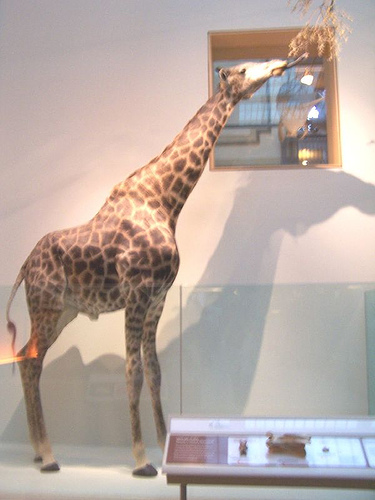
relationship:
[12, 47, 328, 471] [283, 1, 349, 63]
giraffe eating leaves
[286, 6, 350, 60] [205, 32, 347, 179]
branch near window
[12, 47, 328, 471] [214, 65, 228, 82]
giraffe has ears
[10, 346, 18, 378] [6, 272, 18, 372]
hair on tail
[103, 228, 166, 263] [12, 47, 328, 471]
spots on giraffe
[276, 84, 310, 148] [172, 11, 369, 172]
reflection on window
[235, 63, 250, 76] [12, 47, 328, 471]
eye of giraffe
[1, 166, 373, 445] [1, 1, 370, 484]
shadow on wall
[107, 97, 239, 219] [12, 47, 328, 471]
long neck of giraffe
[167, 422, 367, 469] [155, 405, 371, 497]
information on podium